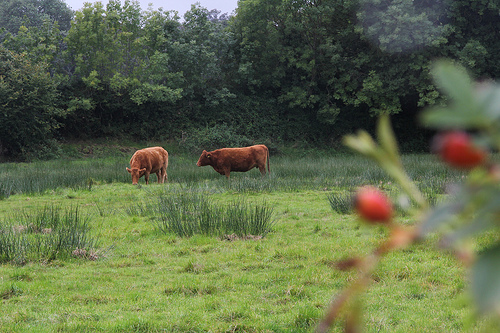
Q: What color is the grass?
A: Green.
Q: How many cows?
A: 2.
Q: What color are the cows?
A: Brown.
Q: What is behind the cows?
A: Trees.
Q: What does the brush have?
A: Flowers.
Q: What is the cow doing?
A: Looking.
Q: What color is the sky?
A: Blue.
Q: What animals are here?
A: Cows.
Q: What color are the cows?
A: Brown.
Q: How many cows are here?
A: 2.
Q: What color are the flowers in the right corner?
A: Red.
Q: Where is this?
A: Grassy field.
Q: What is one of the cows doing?
A: Eating grass.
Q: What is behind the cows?
A: Bushy trees.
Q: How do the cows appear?
A: Well fed.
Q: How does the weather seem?
A: Cool and overcast.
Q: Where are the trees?
A: Behind the cows.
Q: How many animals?
A: 2.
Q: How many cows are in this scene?
A: Two.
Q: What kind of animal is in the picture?
A: Cows.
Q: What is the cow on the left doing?
A: Grazing.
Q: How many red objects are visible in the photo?
A: Two.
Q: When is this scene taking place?
A: Day time.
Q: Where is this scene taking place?
A: Field.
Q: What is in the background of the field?
A: Foliage and brush.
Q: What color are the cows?
A: Brown.